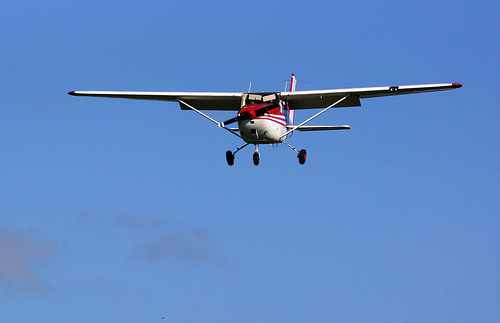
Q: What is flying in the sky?
A: Airplane.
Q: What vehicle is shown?
A: A plane.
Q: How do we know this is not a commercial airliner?
A: The size and shape is wrong.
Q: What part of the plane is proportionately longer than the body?
A: The plane's wings.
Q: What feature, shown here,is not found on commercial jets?
A: The propeller.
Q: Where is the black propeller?
A: On the nose of the plane.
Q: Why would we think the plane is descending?
A: The wheels are showing, indicating the landing gear is ready.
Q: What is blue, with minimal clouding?
A: The sky.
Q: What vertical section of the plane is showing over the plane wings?
A: The plane's tail.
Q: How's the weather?
A: Sunny.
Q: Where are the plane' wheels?
A: Underneath.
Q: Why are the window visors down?
A: The plane is flying into the sun.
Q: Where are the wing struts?
A: Under the wings.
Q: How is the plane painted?
A: Red and white.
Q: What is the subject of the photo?
A: Plane.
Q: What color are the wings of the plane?
A: White.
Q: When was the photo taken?
A: Daytime.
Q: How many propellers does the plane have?
A: One.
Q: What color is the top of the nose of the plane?
A: Red.